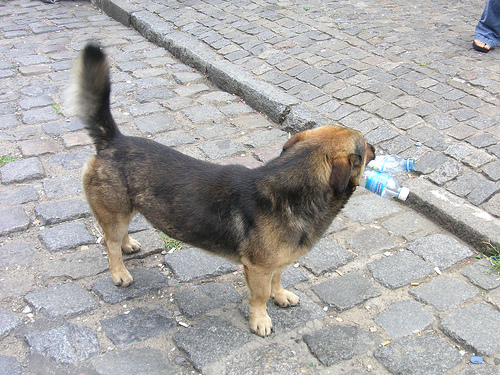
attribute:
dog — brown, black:
[164, 92, 300, 275]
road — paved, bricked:
[1, 1, 471, 371]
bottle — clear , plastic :
[359, 167, 411, 202]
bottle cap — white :
[397, 185, 410, 202]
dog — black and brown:
[78, 42, 377, 338]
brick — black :
[311, 269, 381, 313]